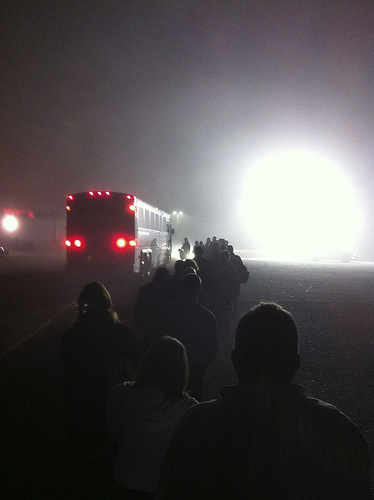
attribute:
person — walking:
[166, 301, 368, 499]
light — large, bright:
[226, 137, 373, 267]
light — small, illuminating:
[0, 208, 20, 234]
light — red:
[119, 238, 126, 248]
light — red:
[73, 238, 82, 248]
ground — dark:
[3, 260, 372, 500]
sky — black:
[0, 0, 373, 198]